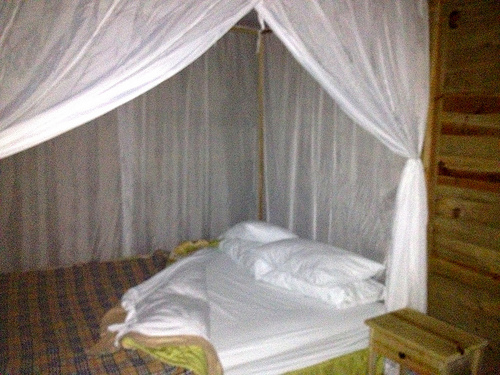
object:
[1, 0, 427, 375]
net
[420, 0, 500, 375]
wall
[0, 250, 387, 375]
bed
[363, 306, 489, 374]
nightstand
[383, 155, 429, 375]
cloth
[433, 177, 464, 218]
ground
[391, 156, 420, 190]
ground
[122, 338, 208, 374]
green object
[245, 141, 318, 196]
wall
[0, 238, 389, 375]
cover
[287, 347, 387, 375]
bed frame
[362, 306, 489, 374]
drawer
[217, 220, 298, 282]
two stacks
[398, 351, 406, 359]
knob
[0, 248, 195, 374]
blanket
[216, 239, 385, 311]
three pillows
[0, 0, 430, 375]
curtains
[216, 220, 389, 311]
pillows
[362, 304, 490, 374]
table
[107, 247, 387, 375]
sheet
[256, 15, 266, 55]
tie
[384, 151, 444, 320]
buttom part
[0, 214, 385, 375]
combo